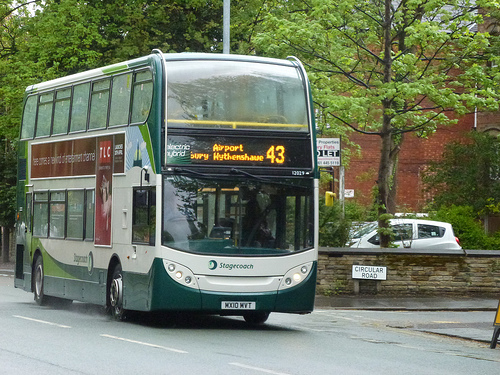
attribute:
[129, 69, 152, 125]
window — small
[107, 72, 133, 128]
window — small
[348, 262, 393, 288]
sign — small, white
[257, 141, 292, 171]
43 — number, orange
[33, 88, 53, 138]
window — small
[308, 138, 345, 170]
sign — green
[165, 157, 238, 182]
wiper — black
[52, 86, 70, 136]
window — small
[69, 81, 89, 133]
window — small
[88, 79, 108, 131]
window — small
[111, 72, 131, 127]
window — small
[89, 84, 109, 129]
window — small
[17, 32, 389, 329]
bus. — green, white, double-decker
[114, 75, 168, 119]
window — small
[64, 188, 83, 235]
window — small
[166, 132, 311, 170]
sign — electronic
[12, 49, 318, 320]
bus — two story, large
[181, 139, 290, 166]
led — orange 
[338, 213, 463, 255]
car — small, silver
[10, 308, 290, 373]
traffic lines — white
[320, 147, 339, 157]
letters — white